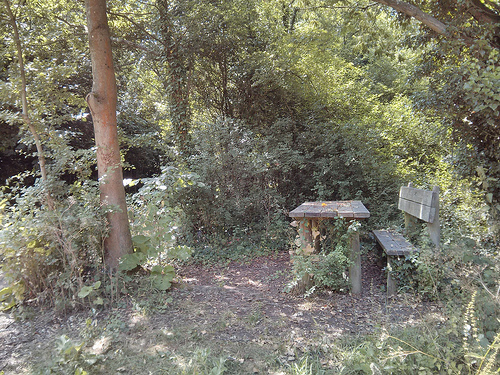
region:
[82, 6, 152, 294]
the tree trunk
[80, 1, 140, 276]
the tree trunk is brown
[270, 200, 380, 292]
a table in the woods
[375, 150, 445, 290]
a bench in the woods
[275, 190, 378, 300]
the table is wooden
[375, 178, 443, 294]
the bench is wooden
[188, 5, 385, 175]
trees with green leaves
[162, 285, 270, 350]
dirt on the ground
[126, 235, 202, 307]
weeds beside the tree trunk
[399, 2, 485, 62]
a tree branch is leaning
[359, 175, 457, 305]
this is the bench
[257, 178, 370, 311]
this is the table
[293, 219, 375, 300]
these are the table legs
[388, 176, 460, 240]
the back of the bench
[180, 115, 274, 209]
these are the shrubs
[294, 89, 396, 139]
these are the leaves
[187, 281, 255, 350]
this is the dirt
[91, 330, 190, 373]
this is the grass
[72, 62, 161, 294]
this is the tree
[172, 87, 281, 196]
this is green vegetation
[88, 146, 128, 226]
stem of a tree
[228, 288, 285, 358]
part of a ground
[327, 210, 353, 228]
edge of a table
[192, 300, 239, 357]
part of a ground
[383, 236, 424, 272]
edge of a bench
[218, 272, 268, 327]
part of a ground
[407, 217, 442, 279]
part of a bench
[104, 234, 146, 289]
part of a plant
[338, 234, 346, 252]
part of a table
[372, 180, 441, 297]
wooden bench in front of the table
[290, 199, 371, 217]
brown leave on top of wood table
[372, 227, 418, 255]
leaves on the seat of the bench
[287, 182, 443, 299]
wooden table and bench set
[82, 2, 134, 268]
the lower part of a tall tree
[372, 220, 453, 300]
tall weeds on the side of bench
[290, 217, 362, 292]
weeds on the side of the table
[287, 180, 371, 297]
wooden table surrounded with weeds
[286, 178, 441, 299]
leaves and weeds on the table and bench set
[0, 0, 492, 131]
yellow and green leaves on the trees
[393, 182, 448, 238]
Wood backing on bench.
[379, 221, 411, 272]
Seat on bench is wood.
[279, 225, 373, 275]
Legs of table are wood.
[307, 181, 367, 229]
Table top is made of wood.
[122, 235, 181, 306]
Large green leaves on plants.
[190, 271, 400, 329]
Ground around table and bench is dirt.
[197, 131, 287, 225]
Green leaves on plants.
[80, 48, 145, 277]
Brown tall tree trunk.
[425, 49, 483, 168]
Green leaves on trees.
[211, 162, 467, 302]
Table and bench in woods.